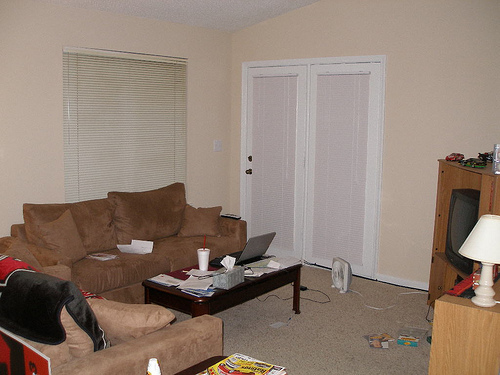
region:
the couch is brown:
[27, 191, 316, 281]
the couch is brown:
[26, 250, 160, 364]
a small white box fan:
[324, 242, 362, 310]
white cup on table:
[180, 230, 235, 305]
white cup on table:
[144, 230, 231, 321]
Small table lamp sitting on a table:
[454, 211, 499, 307]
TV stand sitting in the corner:
[427, 158, 499, 310]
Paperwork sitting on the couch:
[115, 240, 154, 255]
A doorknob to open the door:
[244, 168, 253, 175]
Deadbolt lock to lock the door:
[246, 154, 251, 161]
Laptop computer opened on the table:
[205, 228, 278, 273]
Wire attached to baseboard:
[304, 260, 431, 293]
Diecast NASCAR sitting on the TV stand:
[444, 152, 464, 162]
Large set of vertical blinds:
[59, 45, 194, 204]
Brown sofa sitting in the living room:
[0, 182, 248, 305]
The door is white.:
[231, 53, 384, 279]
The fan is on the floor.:
[328, 258, 352, 290]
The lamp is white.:
[456, 219, 496, 305]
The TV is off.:
[439, 189, 474, 276]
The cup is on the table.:
[187, 243, 214, 266]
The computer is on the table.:
[212, 238, 275, 270]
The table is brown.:
[144, 269, 318, 324]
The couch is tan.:
[24, 189, 249, 262]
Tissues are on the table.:
[208, 255, 246, 289]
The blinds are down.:
[53, 48, 200, 198]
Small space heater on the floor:
[330, 259, 352, 294]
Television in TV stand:
[443, 188, 480, 275]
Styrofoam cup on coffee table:
[197, 236, 210, 271]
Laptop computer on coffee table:
[219, 230, 277, 263]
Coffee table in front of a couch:
[139, 248, 301, 318]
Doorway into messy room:
[237, 52, 305, 279]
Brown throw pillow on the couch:
[180, 205, 222, 233]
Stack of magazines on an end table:
[195, 351, 285, 373]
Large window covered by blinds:
[60, 46, 191, 205]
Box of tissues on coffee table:
[211, 253, 245, 290]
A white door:
[243, 66, 301, 260]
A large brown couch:
[7, 181, 247, 303]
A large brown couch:
[0, 255, 224, 373]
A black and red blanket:
[0, 250, 107, 350]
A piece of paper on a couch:
[114, 234, 156, 255]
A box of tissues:
[211, 256, 247, 290]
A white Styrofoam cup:
[196, 247, 211, 269]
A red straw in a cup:
[200, 235, 210, 250]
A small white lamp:
[458, 214, 498, 306]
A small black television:
[441, 189, 478, 274]